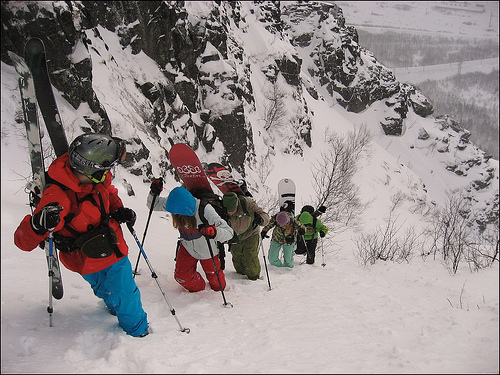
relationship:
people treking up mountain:
[13, 132, 329, 336] [2, 1, 500, 375]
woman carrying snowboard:
[146, 176, 233, 291] [166, 141, 214, 194]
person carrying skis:
[15, 133, 149, 339] [7, 37, 66, 298]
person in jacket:
[15, 133, 149, 339] [13, 151, 128, 276]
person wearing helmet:
[15, 133, 149, 339] [67, 132, 125, 186]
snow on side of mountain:
[2, 1, 500, 374] [2, 1, 500, 375]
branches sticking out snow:
[356, 189, 498, 275] [2, 1, 500, 374]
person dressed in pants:
[259, 210, 304, 268] [268, 238, 295, 270]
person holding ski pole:
[15, 133, 149, 339] [124, 219, 189, 333]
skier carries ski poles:
[146, 176, 233, 291] [133, 176, 231, 306]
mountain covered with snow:
[2, 1, 500, 375] [2, 1, 500, 374]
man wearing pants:
[15, 133, 149, 339] [80, 256, 150, 337]